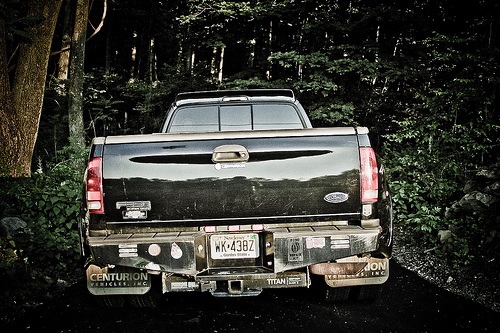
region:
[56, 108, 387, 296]
this is the truck bed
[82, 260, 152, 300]
rubber tire flap with a metal edge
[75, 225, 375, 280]
this is the bumper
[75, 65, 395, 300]
this is a Ford pickup truck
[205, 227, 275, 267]
this is the license plate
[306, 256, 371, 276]
this is an exhaust pipe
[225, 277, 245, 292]
this is a trailer mount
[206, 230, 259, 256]
a New Jersey license plate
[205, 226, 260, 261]
the license plate is white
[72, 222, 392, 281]
there are stickers on the bumper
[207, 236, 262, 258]
a license plate on the back of a truck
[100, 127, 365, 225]
a tailgate on the back of a truck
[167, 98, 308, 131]
the back window of a black truck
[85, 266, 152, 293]
a black and white bumper sticker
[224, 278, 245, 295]
a trailer hitch receptacle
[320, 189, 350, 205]
a blue ford logo on the tailgate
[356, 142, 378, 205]
the right brake light of a black truck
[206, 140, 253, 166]
the handle for a tailgate on a truck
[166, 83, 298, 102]
a rack on top of a truck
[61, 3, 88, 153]
a tree growing in a forested area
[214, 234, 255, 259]
license plate on truck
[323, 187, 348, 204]
ford logo on back of truck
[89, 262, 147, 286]
bumper sticker on truck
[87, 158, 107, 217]
left brake light on truck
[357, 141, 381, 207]
right brake light on truck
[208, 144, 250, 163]
handle to bed of truck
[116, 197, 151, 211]
model name of truck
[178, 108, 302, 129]
back window on truck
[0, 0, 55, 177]
bark of tree on side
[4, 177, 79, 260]
leaves on the bush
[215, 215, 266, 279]
This license plate is from New Jersey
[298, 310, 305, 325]
There is a large patch of asphalt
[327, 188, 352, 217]
There is a Ford sign here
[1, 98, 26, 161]
There is a brown trunk that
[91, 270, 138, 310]
The word "Centurion" is vivid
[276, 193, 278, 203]
This truck has a black color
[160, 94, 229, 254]
This photo has a great deal of detail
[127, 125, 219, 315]
This photo was taken with a telephoto lens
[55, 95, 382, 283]
Truck in the woods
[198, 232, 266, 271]
Number plate on the truck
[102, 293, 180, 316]
Tire of a truck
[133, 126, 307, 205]
Black color of a truck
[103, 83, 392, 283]
A black truck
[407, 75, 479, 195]
Trees in the woods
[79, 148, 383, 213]
Rear lights of a truck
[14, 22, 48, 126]
A tree trunk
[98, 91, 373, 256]
A truck parked in the woods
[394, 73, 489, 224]
Trees in the forest